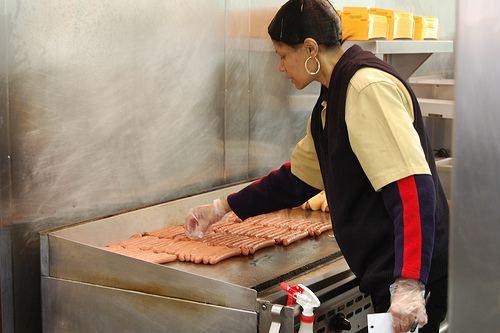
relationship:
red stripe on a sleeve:
[400, 177, 424, 280] [352, 76, 437, 281]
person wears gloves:
[183, 1, 449, 332] [187, 194, 215, 240]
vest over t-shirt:
[307, 43, 447, 292] [289, 69, 432, 191]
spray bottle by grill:
[278, 279, 321, 333] [43, 171, 379, 332]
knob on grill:
[331, 306, 353, 331] [43, 171, 379, 332]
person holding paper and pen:
[183, 1, 449, 332] [368, 287, 443, 333]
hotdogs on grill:
[111, 206, 331, 263] [43, 171, 379, 332]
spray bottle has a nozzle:
[278, 279, 321, 333] [281, 278, 301, 301]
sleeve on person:
[352, 76, 437, 281] [183, 1, 449, 332]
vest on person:
[307, 43, 447, 292] [183, 1, 449, 332]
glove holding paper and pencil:
[391, 279, 431, 332] [368, 287, 443, 333]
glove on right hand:
[187, 194, 215, 240] [186, 195, 234, 239]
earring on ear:
[307, 52, 321, 77] [304, 39, 321, 57]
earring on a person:
[307, 52, 321, 77] [183, 1, 449, 332]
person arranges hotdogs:
[183, 1, 449, 332] [111, 206, 331, 263]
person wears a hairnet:
[183, 1, 449, 332] [269, 2, 345, 45]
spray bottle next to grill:
[278, 279, 321, 333] [43, 171, 379, 332]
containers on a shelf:
[340, 5, 442, 41] [349, 39, 453, 80]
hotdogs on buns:
[111, 206, 331, 263] [298, 190, 334, 216]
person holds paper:
[183, 1, 449, 332] [367, 312, 396, 327]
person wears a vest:
[183, 1, 449, 332] [307, 43, 447, 292]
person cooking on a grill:
[183, 1, 449, 332] [43, 171, 379, 332]